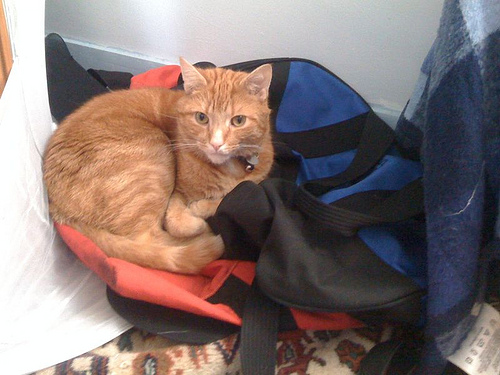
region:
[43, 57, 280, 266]
orange tabby cat curled up near luggage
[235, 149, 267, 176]
small bell on tabby's neck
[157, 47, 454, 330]
empty blue and black duffle bag near cat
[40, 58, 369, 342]
orange and black duffle bag with cat sitting on top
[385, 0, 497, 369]
blue plaid blanket with white tag attached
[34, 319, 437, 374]
wool rug with cream, maroon and blue patterns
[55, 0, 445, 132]
white baseboard and wall in room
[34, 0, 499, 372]
indoor scene with orange tabby sitting on top of empty luggage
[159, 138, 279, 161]
white whiskers on orange cat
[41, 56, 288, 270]
cat shown in curled up position laying down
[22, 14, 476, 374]
a cat laying on a book bag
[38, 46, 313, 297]
an orange cat with bells on a collar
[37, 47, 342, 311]
a short haired orange cat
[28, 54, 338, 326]
a short haired orange tabby cat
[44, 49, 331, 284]
a short haired orange tiger cat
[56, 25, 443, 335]
cat sitting on a blue, black, and orange book bag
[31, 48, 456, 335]
an orange cat laying on a duffle bag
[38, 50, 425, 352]
a short haired tabby resting on a duffle bag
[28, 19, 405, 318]
an orange cat with orange eyes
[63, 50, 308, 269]
cat is on bag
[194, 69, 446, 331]
black and blue bag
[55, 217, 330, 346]
red bag under cat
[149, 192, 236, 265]
cat has orange paws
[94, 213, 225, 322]
cat has orange tail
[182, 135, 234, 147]
cat has orange nose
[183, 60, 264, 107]
cat has orange ears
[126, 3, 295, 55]
white wall behind cat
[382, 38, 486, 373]
blue blanket near bags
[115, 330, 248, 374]
carpet is brown and tan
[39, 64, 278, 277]
small brown cat lying in the floor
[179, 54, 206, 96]
small furry left ear of cat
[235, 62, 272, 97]
small furry right ear of cat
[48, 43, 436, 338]
black red and blue backpack in the floor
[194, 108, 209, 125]
black and yellow left eye of cat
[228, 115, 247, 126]
black and yellow right eye of cat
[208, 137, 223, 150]
small pinky nose of cat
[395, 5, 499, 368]
dark and light blue cloth hanging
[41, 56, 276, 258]
small furry eye lying on a backpack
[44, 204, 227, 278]
large furry tail of cat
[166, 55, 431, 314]
black and blue bag near the cat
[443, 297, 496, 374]
white tag on the piece of clothing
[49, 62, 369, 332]
red and black bag under the cat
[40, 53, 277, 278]
orange cat on the bags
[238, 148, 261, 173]
tag on the collar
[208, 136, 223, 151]
nose on the cat's face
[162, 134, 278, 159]
white whiskers on the cat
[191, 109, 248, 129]
eyes on the cat's face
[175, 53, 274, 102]
ears on the cat's head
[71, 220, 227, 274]
orange cat's tail